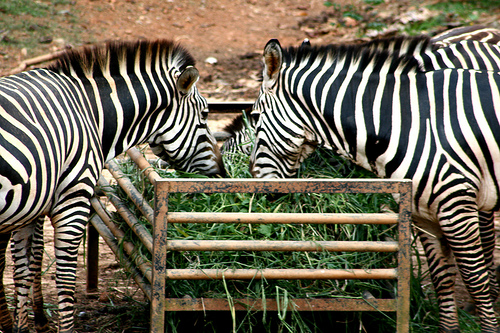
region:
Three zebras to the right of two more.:
[223, 23, 498, 330]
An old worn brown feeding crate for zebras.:
[87, 98, 414, 332]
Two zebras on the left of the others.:
[0, 37, 220, 330]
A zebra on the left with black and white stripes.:
[0, 37, 225, 331]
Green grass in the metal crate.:
[123, 153, 401, 331]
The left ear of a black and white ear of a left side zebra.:
[260, 39, 284, 90]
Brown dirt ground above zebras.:
[84, 3, 348, 58]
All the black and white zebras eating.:
[1, 25, 499, 330]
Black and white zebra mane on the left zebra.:
[43, 38, 192, 76]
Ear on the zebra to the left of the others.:
[173, 65, 200, 97]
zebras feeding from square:
[5, 18, 489, 320]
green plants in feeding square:
[135, 163, 381, 288]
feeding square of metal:
[122, 147, 422, 326]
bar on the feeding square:
[166, 208, 402, 225]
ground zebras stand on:
[1, 247, 131, 324]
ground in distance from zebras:
[93, 5, 325, 37]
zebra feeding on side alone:
[4, 40, 222, 323]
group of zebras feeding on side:
[246, 2, 498, 327]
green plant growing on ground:
[336, 10, 450, 32]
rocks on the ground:
[160, 16, 244, 25]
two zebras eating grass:
[110, 32, 420, 220]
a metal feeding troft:
[77, 179, 410, 331]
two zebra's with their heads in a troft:
[140, 33, 357, 231]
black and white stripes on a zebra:
[344, 61, 448, 140]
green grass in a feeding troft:
[165, 190, 346, 257]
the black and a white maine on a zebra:
[40, 36, 180, 81]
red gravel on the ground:
[114, 8, 321, 42]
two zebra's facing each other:
[155, 43, 322, 183]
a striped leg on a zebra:
[35, 174, 84, 331]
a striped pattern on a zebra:
[348, 79, 472, 141]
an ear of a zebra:
[164, 66, 201, 93]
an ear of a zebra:
[251, 37, 288, 83]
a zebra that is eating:
[1, 26, 218, 328]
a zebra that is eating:
[254, 34, 490, 321]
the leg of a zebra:
[49, 212, 81, 329]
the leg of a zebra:
[5, 224, 30, 331]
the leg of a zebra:
[28, 222, 43, 319]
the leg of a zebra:
[434, 241, 456, 332]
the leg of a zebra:
[451, 180, 493, 328]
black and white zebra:
[2, 34, 125, 157]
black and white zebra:
[312, 66, 465, 203]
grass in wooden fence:
[174, 151, 371, 304]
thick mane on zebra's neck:
[284, 32, 385, 72]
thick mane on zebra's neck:
[61, 25, 176, 96]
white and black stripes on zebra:
[22, 87, 106, 144]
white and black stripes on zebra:
[352, 93, 444, 152]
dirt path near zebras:
[155, 9, 317, 80]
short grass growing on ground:
[4, 16, 52, 44]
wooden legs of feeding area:
[79, 209, 106, 306]